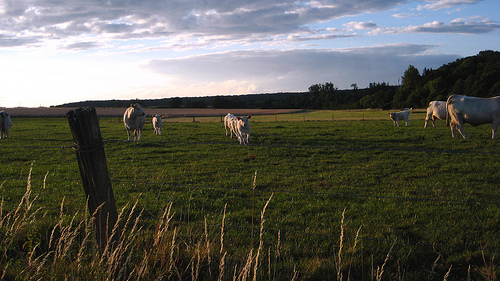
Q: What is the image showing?
A: It is showing a field.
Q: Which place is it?
A: It is a field.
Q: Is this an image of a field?
A: Yes, it is showing a field.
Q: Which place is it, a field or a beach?
A: It is a field.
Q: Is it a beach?
A: No, it is a field.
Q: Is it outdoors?
A: Yes, it is outdoors.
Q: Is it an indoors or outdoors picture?
A: It is outdoors.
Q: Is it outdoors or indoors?
A: It is outdoors.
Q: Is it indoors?
A: No, it is outdoors.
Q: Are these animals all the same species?
A: Yes, all the animals are cows.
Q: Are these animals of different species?
A: No, all the animals are cows.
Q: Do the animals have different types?
A: No, all the animals are cows.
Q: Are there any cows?
A: Yes, there are cows.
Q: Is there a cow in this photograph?
A: Yes, there are cows.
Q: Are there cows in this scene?
A: Yes, there are cows.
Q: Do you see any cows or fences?
A: Yes, there are cows.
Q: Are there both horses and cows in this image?
A: No, there are cows but no horses.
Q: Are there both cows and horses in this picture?
A: No, there are cows but no horses.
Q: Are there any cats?
A: No, there are no cats.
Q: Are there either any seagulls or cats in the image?
A: No, there are no cats or seagulls.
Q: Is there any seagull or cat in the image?
A: No, there are no cats or seagulls.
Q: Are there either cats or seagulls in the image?
A: No, there are no cats or seagulls.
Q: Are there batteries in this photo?
A: No, there are no batteries.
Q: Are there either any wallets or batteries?
A: No, there are no batteries or wallets.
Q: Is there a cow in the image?
A: Yes, there is a cow.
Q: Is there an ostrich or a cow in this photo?
A: Yes, there is a cow.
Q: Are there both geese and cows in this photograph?
A: No, there is a cow but no geese.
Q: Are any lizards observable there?
A: No, there are no lizards.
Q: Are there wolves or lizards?
A: No, there are no lizards or wolves.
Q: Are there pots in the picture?
A: No, there are no pots.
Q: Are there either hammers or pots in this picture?
A: No, there are no pots or hammers.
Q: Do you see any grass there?
A: Yes, there is grass.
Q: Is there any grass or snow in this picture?
A: Yes, there is grass.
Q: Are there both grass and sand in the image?
A: No, there is grass but no sand.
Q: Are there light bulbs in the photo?
A: No, there are no light bulbs.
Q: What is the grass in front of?
A: The grass is in front of the tree.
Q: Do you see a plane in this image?
A: No, there are no airplanes.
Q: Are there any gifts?
A: No, there are no gifts.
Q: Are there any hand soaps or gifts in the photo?
A: No, there are no gifts or hand soaps.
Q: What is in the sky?
A: The clouds are in the sky.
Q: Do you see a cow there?
A: Yes, there is a cow.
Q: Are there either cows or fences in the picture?
A: Yes, there is a cow.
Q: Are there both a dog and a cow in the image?
A: No, there is a cow but no dogs.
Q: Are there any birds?
A: No, there are no birds.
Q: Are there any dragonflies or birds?
A: No, there are no birds or dragonflies.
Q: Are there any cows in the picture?
A: Yes, there is a cow.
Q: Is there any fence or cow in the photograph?
A: Yes, there is a cow.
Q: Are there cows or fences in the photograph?
A: Yes, there is a cow.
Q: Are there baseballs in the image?
A: No, there are no baseballs.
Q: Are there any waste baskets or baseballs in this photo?
A: No, there are no baseballs or waste baskets.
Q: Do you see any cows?
A: Yes, there is a cow.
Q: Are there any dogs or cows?
A: Yes, there is a cow.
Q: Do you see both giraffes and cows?
A: No, there is a cow but no giraffes.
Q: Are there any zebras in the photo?
A: No, there are no zebras.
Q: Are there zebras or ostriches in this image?
A: No, there are no zebras or ostriches.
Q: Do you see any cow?
A: Yes, there is a cow.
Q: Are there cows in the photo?
A: Yes, there is a cow.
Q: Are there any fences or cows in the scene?
A: Yes, there is a cow.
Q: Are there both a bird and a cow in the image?
A: No, there is a cow but no birds.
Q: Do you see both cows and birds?
A: No, there is a cow but no birds.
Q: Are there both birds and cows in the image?
A: No, there is a cow but no birds.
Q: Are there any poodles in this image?
A: No, there are no poodles.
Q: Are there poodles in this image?
A: No, there are no poodles.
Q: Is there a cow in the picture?
A: Yes, there is a cow.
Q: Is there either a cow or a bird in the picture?
A: Yes, there is a cow.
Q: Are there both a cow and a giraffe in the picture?
A: No, there is a cow but no giraffes.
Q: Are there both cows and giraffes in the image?
A: No, there is a cow but no giraffes.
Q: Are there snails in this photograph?
A: No, there are no snails.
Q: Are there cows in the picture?
A: Yes, there is a cow.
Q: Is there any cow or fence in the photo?
A: Yes, there is a cow.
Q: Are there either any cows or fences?
A: Yes, there is a cow.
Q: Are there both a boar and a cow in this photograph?
A: No, there is a cow but no boars.